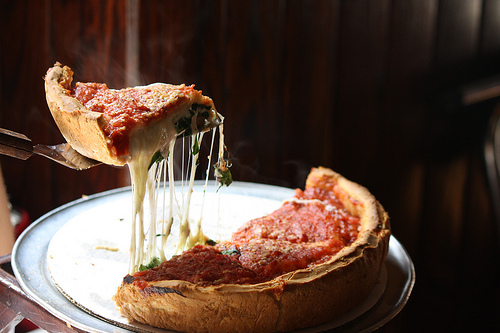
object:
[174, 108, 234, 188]
spinach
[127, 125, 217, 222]
cheese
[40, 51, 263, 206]
food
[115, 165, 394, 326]
pizza